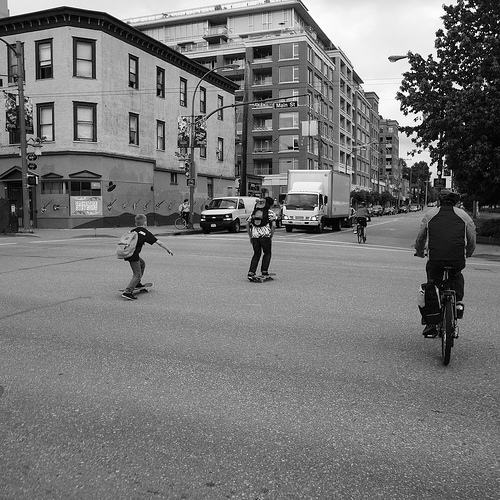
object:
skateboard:
[116, 280, 155, 295]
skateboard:
[245, 270, 278, 284]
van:
[198, 194, 263, 235]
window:
[72, 100, 97, 125]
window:
[72, 121, 97, 143]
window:
[177, 90, 187, 105]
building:
[0, 0, 242, 230]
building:
[114, 1, 414, 212]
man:
[411, 188, 478, 339]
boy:
[114, 210, 176, 302]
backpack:
[114, 229, 139, 261]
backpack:
[245, 194, 274, 240]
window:
[41, 65, 54, 80]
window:
[35, 122, 57, 140]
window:
[127, 52, 139, 78]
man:
[351, 197, 371, 245]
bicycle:
[350, 217, 368, 245]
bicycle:
[416, 259, 465, 368]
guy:
[244, 194, 278, 285]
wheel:
[439, 293, 457, 368]